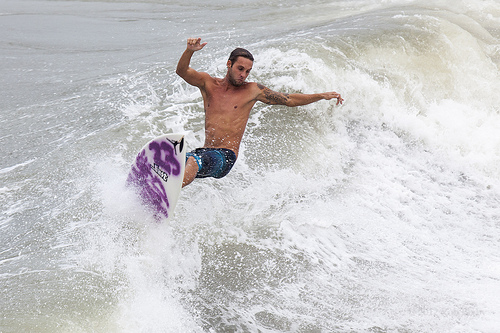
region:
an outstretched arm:
[259, 87, 346, 107]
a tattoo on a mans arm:
[258, 84, 292, 111]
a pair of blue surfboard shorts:
[183, 145, 238, 181]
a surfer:
[172, 32, 342, 187]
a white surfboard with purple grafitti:
[121, 133, 185, 227]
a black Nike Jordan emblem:
[164, 138, 183, 153]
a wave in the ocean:
[109, 7, 479, 306]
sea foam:
[286, 58, 485, 253]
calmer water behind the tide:
[1, 2, 146, 72]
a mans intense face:
[229, 50, 254, 87]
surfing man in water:
[129, 40, 271, 207]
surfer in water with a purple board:
[146, 37, 260, 202]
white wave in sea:
[103, 38, 455, 330]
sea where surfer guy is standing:
[0, 12, 494, 323]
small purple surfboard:
[127, 130, 194, 220]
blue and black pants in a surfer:
[179, 144, 243, 179]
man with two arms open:
[166, 37, 267, 191]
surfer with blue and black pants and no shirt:
[166, 37, 273, 188]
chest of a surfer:
[202, 72, 262, 144]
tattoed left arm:
[262, 80, 337, 112]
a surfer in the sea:
[149, 26, 363, 208]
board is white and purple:
[113, 127, 193, 239]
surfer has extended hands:
[142, 29, 357, 194]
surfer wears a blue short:
[154, 26, 353, 205]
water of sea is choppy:
[20, 11, 497, 331]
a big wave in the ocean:
[91, 11, 483, 311]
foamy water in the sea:
[250, 83, 498, 330]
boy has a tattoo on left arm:
[166, 31, 356, 131]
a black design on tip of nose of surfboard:
[143, 124, 197, 167]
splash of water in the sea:
[71, 129, 197, 307]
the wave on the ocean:
[69, 16, 499, 270]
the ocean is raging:
[43, 19, 456, 303]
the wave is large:
[96, 7, 483, 284]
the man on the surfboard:
[119, 17, 354, 232]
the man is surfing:
[103, 26, 363, 230]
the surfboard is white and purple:
[86, 122, 224, 232]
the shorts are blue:
[177, 140, 242, 180]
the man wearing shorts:
[130, 46, 281, 203]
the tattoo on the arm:
[241, 80, 299, 115]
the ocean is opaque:
[53, 14, 125, 56]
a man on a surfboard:
[91, 5, 369, 230]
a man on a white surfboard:
[65, 7, 386, 262]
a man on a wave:
[64, 4, 389, 276]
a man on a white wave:
[32, 20, 489, 242]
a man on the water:
[28, 28, 478, 221]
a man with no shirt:
[94, 10, 464, 221]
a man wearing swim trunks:
[107, 11, 367, 226]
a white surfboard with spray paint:
[61, 97, 243, 230]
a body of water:
[272, 32, 499, 317]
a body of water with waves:
[342, 52, 493, 329]